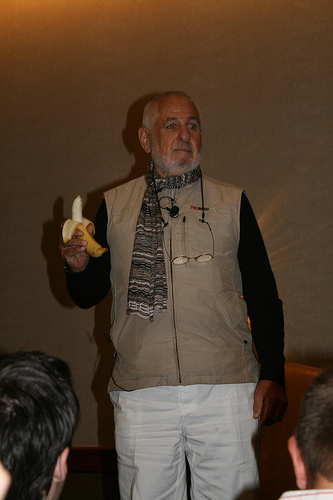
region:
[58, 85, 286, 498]
a man standing with a banana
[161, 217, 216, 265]
glasses resting on the man's chest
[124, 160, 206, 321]
scarf around the man's neck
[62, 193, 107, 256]
a whole banana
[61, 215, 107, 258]
a yellow banana peel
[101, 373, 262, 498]
the man's white pants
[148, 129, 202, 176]
the man's facial hair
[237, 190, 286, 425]
the man's left arm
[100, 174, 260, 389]
the mans light brown vest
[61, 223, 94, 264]
the man's fingers on the banana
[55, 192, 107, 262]
half peeled banana man is holding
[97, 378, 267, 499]
white wrinkled pants of man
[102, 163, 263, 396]
tan vest jacket of man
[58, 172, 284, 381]
dark colored sleeves of man's hirt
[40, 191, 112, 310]
shadow of man and banana on wall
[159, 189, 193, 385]
zipper of tan vest jacket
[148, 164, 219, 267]
glasses hanging around man's neck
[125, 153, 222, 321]
scarf around man's neck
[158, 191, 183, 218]
black microphone clipped to man's jacket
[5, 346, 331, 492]
two men sitting in audience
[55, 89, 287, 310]
The man is holding a banana.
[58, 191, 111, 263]
The banana is partially peeled.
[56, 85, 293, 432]
The man is wearing a vest.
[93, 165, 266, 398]
The vest zips up the front.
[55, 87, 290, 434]
The man is wearing a scarf.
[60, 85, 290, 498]
The man is wearing pants.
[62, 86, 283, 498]
The man's pants are white.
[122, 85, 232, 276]
Man's glasses are hanging from neck.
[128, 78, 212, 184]
The man is balding.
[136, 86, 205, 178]
The man has a moustache.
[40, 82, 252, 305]
man holding a banana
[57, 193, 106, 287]
banana has been peeled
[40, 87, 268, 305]
man holding banana with right hand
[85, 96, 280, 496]
man wearing white pants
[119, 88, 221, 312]
man has knitted scarf around his neck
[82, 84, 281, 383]
man is wearing a tan vest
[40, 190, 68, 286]
shadow of banana on wall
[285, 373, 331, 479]
partial view of back of someone's head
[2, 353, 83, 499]
partial back view of someone's head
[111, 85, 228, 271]
man has glasses around his neck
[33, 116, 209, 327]
man holding a banana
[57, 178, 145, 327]
man holding a banana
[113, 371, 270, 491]
man wearing a pants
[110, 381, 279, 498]
the pants are white